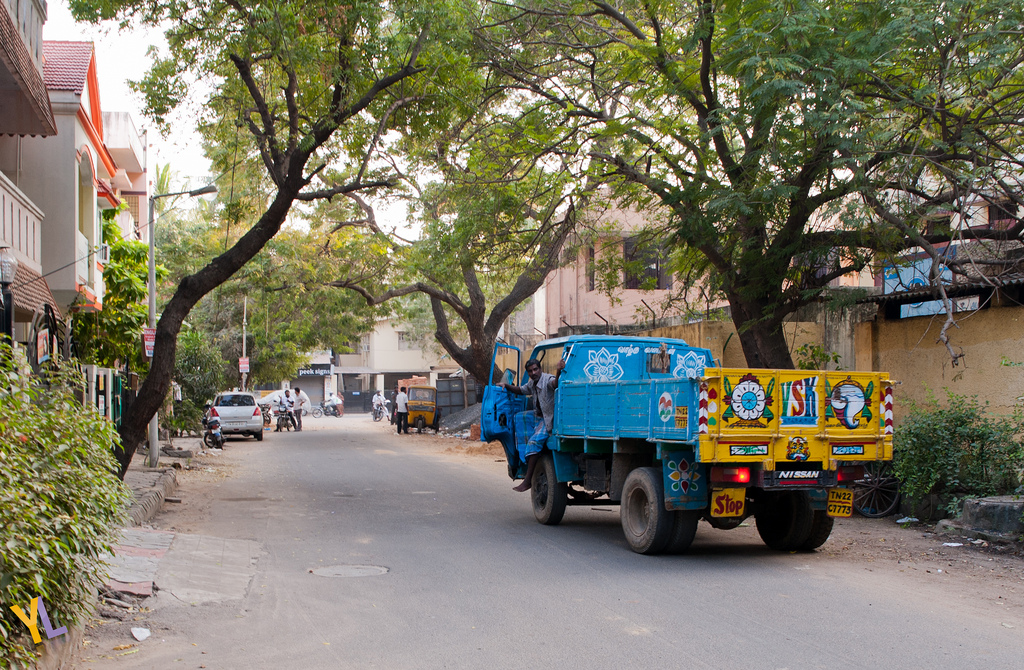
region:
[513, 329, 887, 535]
a truck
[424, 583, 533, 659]
the street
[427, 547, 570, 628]
the street is grey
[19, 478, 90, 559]
the leaves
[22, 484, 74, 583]
the leaves are green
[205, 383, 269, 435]
a grey car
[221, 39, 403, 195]
tree branches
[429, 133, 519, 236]
leaves are green on the tree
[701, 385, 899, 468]
Back of truck is yellow.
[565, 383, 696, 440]
Side of truck bed is blue.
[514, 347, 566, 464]
Person is sitting in truck.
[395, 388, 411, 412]
Person wearing white shirt.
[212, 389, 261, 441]
White car parked on side of road.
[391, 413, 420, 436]
Person wearing black pants.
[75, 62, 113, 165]
Orange trim on white building.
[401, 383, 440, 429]
Small yellow vehicle on side of road.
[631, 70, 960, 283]
Green leaves on tree.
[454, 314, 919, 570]
Truck on the road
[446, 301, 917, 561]
Truck is on the road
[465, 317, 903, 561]
Truck on a street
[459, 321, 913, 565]
Truck is on a street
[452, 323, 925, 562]
Blue and yellow truck on the road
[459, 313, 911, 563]
Blue and yellow truck is on the road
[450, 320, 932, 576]
Blue and yellow truck on the street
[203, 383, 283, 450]
White car is parked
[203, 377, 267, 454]
White car is parked on the side of the road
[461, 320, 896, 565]
a blue and yellow truck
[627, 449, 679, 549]
a black rubber tire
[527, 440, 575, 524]
a black rubber tire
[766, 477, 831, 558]
a black rubber tire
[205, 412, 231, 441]
a black rubber tire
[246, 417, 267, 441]
a black rubber tire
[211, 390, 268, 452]
the back of a white truck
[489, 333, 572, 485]
the door of a blue truck